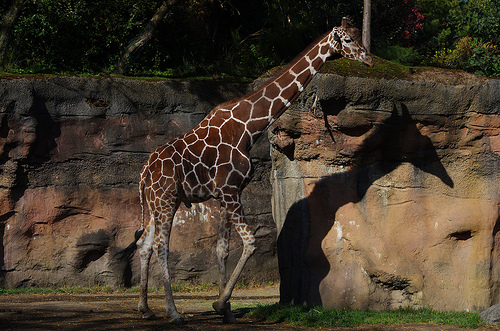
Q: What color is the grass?
A: Green.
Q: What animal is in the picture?
A: Giraffe.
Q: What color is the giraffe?
A: White and brown.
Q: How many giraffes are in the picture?
A: One.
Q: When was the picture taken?
A: During the day.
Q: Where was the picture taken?
A: At a zoo.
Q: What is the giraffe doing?
A: Walking.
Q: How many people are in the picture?
A: Zero.